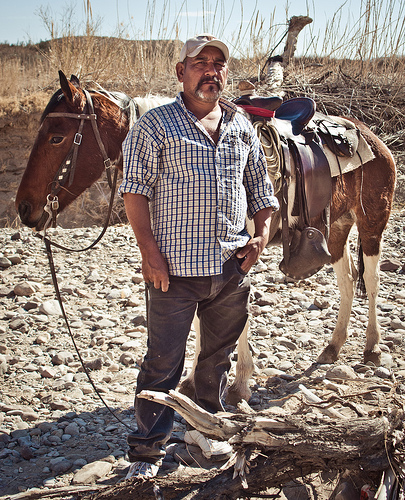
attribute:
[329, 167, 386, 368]
legs — white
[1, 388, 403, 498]
wood — dead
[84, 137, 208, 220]
sleeves — rolled up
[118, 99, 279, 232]
shirt — plaid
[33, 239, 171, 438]
strap — dangling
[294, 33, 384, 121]
weed — tall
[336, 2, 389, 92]
weed — tall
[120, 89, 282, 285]
shirt — checkered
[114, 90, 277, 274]
shirt — blue, white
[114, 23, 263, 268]
man — standing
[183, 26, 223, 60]
cap — white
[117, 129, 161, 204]
sleeve — rolled up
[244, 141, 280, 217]
sleeve — rolled up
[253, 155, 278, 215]
sleeve — long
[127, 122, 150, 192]
sleeve — long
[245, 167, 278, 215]
sleeve — rolled up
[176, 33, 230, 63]
hat — white